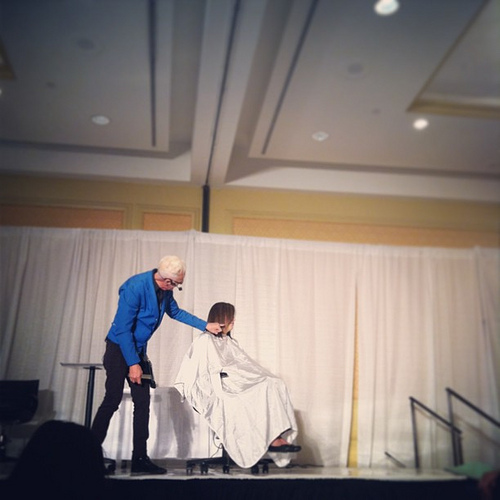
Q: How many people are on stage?
A: Two.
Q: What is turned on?
A: Lights.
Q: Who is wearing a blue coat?
A: Man on stage.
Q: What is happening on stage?
A: A demonstration.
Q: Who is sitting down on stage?
A: A woman.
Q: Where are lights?
A: On the ceiling.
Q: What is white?
A: A curtain.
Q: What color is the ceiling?
A: White.